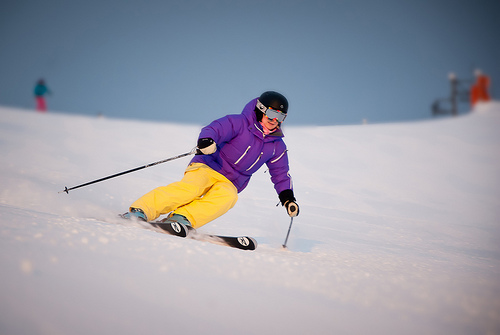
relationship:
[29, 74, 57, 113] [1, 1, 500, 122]
skier in background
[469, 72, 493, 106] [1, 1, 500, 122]
skier in background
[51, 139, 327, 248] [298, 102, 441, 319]
skiing down slope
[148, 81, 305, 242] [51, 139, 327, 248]
person holding poles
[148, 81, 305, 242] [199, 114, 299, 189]
person wearing coat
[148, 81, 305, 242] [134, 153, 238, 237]
person has pants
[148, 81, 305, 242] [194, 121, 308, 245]
person wearing gloves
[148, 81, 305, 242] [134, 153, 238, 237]
skier in pants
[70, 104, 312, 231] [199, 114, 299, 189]
skier in jacket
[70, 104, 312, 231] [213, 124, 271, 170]
skier in purple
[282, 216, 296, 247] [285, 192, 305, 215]
ski pole in hand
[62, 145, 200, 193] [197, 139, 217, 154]
ski pole in hands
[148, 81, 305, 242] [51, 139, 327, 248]
person wearing skis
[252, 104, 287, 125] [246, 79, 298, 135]
goggles around head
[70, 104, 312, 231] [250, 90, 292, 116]
skier wearing helmet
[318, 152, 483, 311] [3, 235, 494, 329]
snow covered ground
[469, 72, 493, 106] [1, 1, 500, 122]
person in background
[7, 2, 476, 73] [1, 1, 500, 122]
sky in background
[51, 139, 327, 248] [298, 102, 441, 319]
skiing down slopes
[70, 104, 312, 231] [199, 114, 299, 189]
skier wearing coat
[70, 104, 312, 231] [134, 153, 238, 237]
skier wearing pants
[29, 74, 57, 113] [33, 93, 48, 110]
skier wearing pants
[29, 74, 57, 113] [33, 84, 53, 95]
skier wearing coat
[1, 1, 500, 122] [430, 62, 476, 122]
background ski lift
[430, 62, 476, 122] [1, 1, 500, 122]
lift in background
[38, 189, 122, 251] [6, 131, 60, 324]
prints in snow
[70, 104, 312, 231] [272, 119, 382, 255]
skier leaning into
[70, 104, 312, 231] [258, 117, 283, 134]
skier happily smiling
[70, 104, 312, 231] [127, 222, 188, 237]
skier wearing ski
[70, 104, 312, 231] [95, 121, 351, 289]
skier making curve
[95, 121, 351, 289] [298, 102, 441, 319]
curve on slope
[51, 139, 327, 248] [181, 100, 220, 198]
poles in back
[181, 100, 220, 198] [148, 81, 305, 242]
back of body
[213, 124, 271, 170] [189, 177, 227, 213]
purple and yellow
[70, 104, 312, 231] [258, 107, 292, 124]
skier with goggles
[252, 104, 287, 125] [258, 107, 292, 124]
goggles over goggles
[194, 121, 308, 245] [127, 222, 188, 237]
leaning on ski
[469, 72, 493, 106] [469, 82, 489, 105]
person wearing red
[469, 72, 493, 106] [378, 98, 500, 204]
person atop hill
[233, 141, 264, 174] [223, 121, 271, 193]
zippers on front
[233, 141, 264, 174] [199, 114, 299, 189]
zippers on jacket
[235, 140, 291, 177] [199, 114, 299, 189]
zippers on jacket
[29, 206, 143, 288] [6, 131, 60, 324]
dots of snow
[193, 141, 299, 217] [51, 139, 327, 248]
hands holding poles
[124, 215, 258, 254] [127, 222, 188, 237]
bottom of ski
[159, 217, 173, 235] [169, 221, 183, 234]
black and white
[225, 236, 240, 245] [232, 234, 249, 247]
black and white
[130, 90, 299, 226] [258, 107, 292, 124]
person wearing goggles